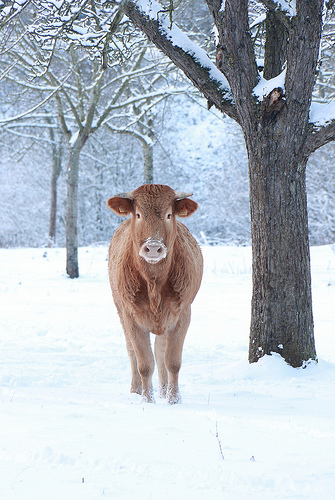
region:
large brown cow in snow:
[95, 175, 210, 411]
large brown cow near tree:
[98, 171, 204, 422]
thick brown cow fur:
[119, 265, 190, 330]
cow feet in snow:
[119, 368, 197, 412]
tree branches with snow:
[188, 44, 331, 161]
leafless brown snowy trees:
[18, 51, 165, 155]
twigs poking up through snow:
[199, 413, 265, 476]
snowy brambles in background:
[201, 171, 245, 241]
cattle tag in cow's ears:
[176, 199, 195, 219]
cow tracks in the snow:
[6, 322, 114, 396]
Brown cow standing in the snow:
[85, 164, 215, 416]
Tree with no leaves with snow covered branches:
[4, 21, 112, 278]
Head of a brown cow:
[94, 180, 213, 269]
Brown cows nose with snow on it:
[131, 233, 180, 265]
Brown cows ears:
[99, 183, 201, 218]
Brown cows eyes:
[132, 202, 181, 226]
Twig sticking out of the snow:
[189, 405, 243, 464]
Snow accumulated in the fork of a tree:
[244, 44, 302, 110]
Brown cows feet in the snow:
[121, 372, 187, 409]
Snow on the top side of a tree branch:
[169, 27, 214, 102]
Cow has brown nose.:
[135, 239, 190, 279]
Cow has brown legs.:
[128, 349, 239, 407]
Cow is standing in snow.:
[103, 358, 216, 447]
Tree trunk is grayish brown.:
[260, 283, 292, 323]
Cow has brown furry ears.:
[99, 177, 218, 229]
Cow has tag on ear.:
[172, 197, 208, 245]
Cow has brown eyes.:
[123, 207, 192, 229]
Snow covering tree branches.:
[26, 20, 107, 85]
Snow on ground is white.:
[94, 443, 163, 479]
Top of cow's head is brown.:
[139, 181, 181, 201]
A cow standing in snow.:
[89, 172, 220, 409]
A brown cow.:
[95, 182, 212, 405]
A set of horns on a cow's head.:
[110, 188, 191, 201]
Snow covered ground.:
[1, 247, 329, 493]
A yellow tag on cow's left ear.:
[177, 205, 190, 216]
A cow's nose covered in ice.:
[137, 236, 167, 261]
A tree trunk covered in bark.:
[214, 2, 333, 389]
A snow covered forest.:
[0, 62, 332, 239]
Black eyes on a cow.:
[133, 210, 173, 221]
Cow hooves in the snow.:
[124, 380, 188, 408]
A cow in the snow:
[103, 167, 210, 405]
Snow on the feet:
[132, 381, 180, 408]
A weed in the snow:
[209, 415, 235, 466]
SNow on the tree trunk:
[245, 329, 296, 353]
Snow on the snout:
[137, 225, 168, 264]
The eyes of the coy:
[131, 204, 175, 227]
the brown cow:
[96, 171, 214, 413]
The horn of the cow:
[172, 187, 197, 200]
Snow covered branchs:
[11, 0, 119, 55]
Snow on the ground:
[23, 264, 60, 412]